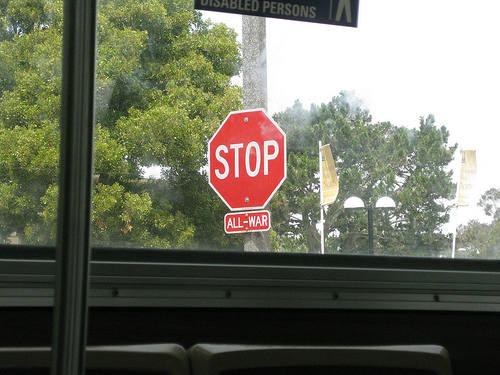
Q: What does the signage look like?
A: It is an octagon that is red with white lettering.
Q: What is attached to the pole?
A: Two signs are attached to the pole.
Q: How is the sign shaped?
A: The sign has 8 sides; octagon.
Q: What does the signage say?
A: The signs says stop.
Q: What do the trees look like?
A: The trees are fully mature and hunter green.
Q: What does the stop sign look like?
A: It is red with white lettering.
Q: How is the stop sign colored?
A: Red and white.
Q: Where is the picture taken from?
A: Inside of a bus.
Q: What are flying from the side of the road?
A: Flags.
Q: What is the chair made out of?
A: Plastic.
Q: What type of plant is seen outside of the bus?
A: Trees.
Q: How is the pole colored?
A: Gray.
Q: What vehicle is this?
A: Bus.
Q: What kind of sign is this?
A: Stop sign.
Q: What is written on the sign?
A: STOP.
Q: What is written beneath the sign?
A: All-War.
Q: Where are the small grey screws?
A: In the stop sign.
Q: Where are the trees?
A: Behind the sign.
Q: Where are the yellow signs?
A: By the stop sign.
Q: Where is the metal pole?
A: Behind the stop sign.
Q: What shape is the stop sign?
A: Octagon.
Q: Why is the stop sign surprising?
A: Because it says "all-war.".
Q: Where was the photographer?
A: In a vehicle.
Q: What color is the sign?
A: Red.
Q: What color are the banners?
A: Yellow.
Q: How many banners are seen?
A: Two.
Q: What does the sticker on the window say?
A: Disabled persons.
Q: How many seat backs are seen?
A: Two.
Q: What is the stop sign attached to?
A: A pole.